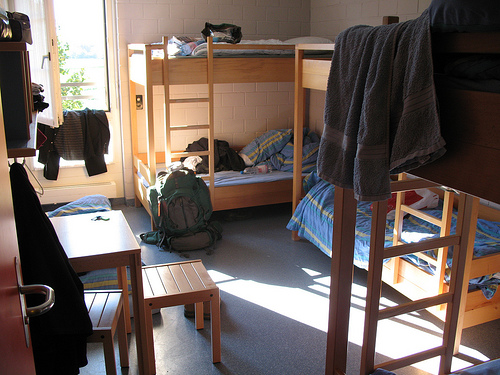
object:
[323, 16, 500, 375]
bed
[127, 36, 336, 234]
bed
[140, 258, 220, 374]
chair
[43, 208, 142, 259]
surface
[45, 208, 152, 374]
table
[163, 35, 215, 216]
ladder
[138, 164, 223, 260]
pack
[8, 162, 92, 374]
jacket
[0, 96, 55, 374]
door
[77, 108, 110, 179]
jacket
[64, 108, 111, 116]
windowsill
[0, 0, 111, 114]
window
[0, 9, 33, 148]
shirts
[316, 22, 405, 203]
towel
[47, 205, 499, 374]
flooring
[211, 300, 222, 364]
leg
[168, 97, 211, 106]
step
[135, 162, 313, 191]
sheet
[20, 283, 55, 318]
handle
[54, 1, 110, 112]
light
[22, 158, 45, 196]
hanger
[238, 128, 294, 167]
pillow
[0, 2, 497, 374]
picture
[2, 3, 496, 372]
day